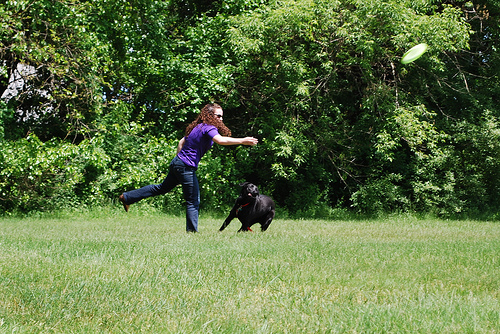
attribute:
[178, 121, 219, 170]
shirt — purple color, purple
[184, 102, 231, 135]
hair — red, long, brown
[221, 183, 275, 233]
dog — playing, black color, black, running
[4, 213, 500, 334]
field — grassy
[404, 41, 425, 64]
frisbee — green color, green, flying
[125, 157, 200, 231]
jeans — blue, blue color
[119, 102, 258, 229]
lady — throwing, playing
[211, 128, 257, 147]
arm — extended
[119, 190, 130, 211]
shoe — brown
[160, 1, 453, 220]
tree — green, rowed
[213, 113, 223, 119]
sunglasses — black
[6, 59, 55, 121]
sky — blue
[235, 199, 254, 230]
leash — red color